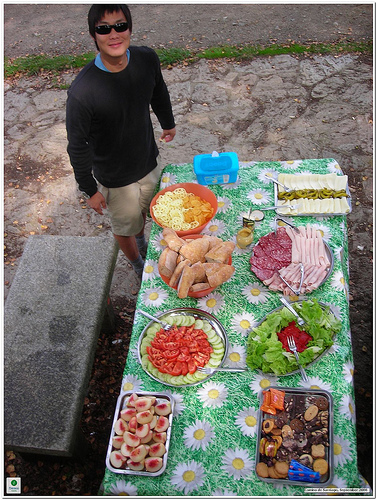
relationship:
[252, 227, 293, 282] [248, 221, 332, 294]
meat on tray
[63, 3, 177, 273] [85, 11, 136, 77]
cookies with a face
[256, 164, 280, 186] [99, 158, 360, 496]
flower on table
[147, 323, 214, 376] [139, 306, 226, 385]
tomatoe on a plate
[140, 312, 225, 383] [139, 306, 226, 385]
cucumbers on a plate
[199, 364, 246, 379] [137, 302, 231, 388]
fork on a plate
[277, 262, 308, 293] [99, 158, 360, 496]
tongs on table